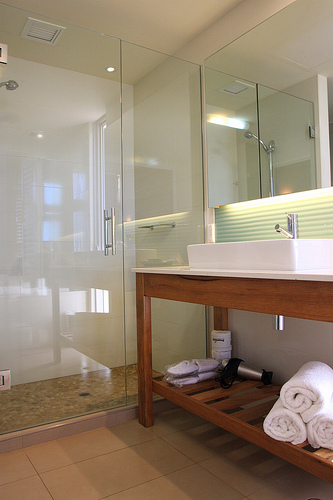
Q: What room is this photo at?
A: It is at the bathroom.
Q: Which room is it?
A: It is a bathroom.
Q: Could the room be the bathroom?
A: Yes, it is the bathroom.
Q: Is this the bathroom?
A: Yes, it is the bathroom.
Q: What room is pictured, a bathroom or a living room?
A: It is a bathroom.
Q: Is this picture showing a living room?
A: No, the picture is showing a bathroom.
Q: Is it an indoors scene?
A: Yes, it is indoors.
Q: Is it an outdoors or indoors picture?
A: It is indoors.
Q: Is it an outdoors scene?
A: No, it is indoors.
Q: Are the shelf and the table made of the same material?
A: Yes, both the shelf and the table are made of wood.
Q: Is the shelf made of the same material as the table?
A: Yes, both the shelf and the table are made of wood.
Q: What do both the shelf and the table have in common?
A: The material, both the shelf and the table are wooden.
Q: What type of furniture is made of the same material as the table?
A: The shelf is made of the same material as the table.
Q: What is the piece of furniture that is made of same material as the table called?
A: The piece of furniture is a shelf.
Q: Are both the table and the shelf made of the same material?
A: Yes, both the table and the shelf are made of wood.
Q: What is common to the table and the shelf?
A: The material, both the table and the shelf are wooden.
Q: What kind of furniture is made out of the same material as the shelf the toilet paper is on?
A: The table is made of the same material as the shelf.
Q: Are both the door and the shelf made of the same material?
A: No, the door is made of glass and the shelf is made of wood.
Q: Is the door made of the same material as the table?
A: No, the door is made of glass and the table is made of wood.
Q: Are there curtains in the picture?
A: No, there are no curtains.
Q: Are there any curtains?
A: No, there are no curtains.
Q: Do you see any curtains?
A: No, there are no curtains.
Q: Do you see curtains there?
A: No, there are no curtains.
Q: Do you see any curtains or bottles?
A: No, there are no curtains or bottles.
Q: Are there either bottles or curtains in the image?
A: No, there are no curtains or bottles.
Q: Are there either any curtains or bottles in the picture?
A: No, there are no curtains or bottles.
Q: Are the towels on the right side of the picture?
A: Yes, the towels are on the right of the image.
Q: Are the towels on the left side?
A: No, the towels are on the right of the image.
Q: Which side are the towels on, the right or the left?
A: The towels are on the right of the image.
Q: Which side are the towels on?
A: The towels are on the right of the image.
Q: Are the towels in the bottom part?
A: Yes, the towels are in the bottom of the image.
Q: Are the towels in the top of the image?
A: No, the towels are in the bottom of the image.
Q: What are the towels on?
A: The towels are on the shelf.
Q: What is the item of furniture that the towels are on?
A: The piece of furniture is a shelf.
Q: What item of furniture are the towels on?
A: The towels are on the shelf.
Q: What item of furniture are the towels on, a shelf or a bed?
A: The towels are on a shelf.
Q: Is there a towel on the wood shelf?
A: Yes, there are towels on the shelf.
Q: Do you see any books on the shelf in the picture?
A: No, there are towels on the shelf.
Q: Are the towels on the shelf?
A: Yes, the towels are on the shelf.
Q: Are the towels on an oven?
A: No, the towels are on the shelf.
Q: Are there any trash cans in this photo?
A: No, there are no trash cans.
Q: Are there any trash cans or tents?
A: No, there are no trash cans or tents.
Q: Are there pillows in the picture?
A: No, there are no pillows.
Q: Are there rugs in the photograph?
A: No, there are no rugs.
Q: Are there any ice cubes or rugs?
A: No, there are no rugs or ice cubes.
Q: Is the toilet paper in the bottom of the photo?
A: Yes, the toilet paper is in the bottom of the image.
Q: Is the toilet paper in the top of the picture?
A: No, the toilet paper is in the bottom of the image.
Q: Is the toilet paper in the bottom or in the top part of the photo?
A: The toilet paper is in the bottom of the image.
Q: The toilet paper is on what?
A: The toilet paper is on the shelf.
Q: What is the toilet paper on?
A: The toilet paper is on the shelf.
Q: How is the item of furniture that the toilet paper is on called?
A: The piece of furniture is a shelf.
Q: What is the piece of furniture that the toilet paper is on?
A: The piece of furniture is a shelf.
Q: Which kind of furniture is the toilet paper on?
A: The toilet paper is on the shelf.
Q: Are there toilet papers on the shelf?
A: Yes, there is a toilet paper on the shelf.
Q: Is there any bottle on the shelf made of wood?
A: No, there is a toilet paper on the shelf.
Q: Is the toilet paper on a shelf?
A: Yes, the toilet paper is on a shelf.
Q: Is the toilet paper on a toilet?
A: No, the toilet paper is on a shelf.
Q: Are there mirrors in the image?
A: Yes, there is a mirror.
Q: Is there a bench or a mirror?
A: Yes, there is a mirror.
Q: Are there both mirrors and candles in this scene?
A: No, there is a mirror but no candles.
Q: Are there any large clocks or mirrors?
A: Yes, there is a large mirror.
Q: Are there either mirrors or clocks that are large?
A: Yes, the mirror is large.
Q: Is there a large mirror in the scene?
A: Yes, there is a large mirror.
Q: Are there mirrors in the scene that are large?
A: Yes, there is a mirror that is large.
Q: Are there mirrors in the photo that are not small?
A: Yes, there is a large mirror.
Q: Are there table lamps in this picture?
A: No, there are no table lamps.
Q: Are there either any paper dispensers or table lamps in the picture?
A: No, there are no table lamps or paper dispensers.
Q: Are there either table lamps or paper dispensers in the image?
A: No, there are no table lamps or paper dispensers.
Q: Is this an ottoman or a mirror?
A: This is a mirror.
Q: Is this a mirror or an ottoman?
A: This is a mirror.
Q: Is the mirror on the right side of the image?
A: Yes, the mirror is on the right of the image.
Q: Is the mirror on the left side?
A: No, the mirror is on the right of the image.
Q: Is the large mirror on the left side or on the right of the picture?
A: The mirror is on the right of the image.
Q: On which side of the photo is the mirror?
A: The mirror is on the right of the image.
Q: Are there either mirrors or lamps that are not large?
A: No, there is a mirror but it is large.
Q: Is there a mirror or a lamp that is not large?
A: No, there is a mirror but it is large.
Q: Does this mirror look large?
A: Yes, the mirror is large.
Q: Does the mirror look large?
A: Yes, the mirror is large.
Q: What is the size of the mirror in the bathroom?
A: The mirror is large.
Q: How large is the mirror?
A: The mirror is large.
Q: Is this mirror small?
A: No, the mirror is large.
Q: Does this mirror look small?
A: No, the mirror is large.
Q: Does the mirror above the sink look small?
A: No, the mirror is large.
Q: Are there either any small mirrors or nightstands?
A: No, there is a mirror but it is large.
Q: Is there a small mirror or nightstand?
A: No, there is a mirror but it is large.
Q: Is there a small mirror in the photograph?
A: No, there is a mirror but it is large.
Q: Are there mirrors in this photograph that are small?
A: No, there is a mirror but it is large.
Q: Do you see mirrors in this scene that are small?
A: No, there is a mirror but it is large.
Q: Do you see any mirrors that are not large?
A: No, there is a mirror but it is large.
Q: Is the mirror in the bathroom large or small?
A: The mirror is large.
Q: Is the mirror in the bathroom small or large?
A: The mirror is large.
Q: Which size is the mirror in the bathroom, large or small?
A: The mirror is large.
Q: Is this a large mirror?
A: Yes, this is a large mirror.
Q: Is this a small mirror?
A: No, this is a large mirror.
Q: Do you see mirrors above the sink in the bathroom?
A: Yes, there is a mirror above the sink.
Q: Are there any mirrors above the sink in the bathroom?
A: Yes, there is a mirror above the sink.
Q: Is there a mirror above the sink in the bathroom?
A: Yes, there is a mirror above the sink.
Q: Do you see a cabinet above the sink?
A: No, there is a mirror above the sink.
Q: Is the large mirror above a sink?
A: Yes, the mirror is above a sink.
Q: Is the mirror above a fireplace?
A: No, the mirror is above a sink.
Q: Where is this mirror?
A: The mirror is in the bathroom.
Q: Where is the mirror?
A: The mirror is in the bathroom.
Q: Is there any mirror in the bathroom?
A: Yes, there is a mirror in the bathroom.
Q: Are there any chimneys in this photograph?
A: No, there are no chimneys.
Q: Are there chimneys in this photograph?
A: No, there are no chimneys.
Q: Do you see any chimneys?
A: No, there are no chimneys.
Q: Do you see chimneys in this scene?
A: No, there are no chimneys.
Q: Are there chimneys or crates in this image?
A: No, there are no chimneys or crates.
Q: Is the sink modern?
A: Yes, the sink is modern.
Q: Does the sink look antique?
A: No, the sink is modern.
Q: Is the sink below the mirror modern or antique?
A: The sink is modern.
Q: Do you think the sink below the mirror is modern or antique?
A: The sink is modern.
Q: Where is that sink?
A: The sink is in the bathroom.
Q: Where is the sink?
A: The sink is in the bathroom.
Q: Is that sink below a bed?
A: No, the sink is below the mirror.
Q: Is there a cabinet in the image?
A: No, there are no cabinets.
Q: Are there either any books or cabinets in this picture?
A: No, there are no cabinets or books.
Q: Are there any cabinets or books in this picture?
A: No, there are no cabinets or books.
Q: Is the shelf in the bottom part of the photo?
A: Yes, the shelf is in the bottom of the image.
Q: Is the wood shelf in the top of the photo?
A: No, the shelf is in the bottom of the image.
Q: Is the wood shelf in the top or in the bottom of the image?
A: The shelf is in the bottom of the image.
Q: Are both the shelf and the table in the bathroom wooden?
A: Yes, both the shelf and the table are wooden.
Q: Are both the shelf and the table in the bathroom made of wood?
A: Yes, both the shelf and the table are made of wood.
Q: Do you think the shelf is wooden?
A: Yes, the shelf is wooden.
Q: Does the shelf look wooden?
A: Yes, the shelf is wooden.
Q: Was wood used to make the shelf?
A: Yes, the shelf is made of wood.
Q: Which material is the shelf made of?
A: The shelf is made of wood.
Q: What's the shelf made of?
A: The shelf is made of wood.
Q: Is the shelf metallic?
A: No, the shelf is wooden.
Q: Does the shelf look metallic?
A: No, the shelf is wooden.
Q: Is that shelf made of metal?
A: No, the shelf is made of wood.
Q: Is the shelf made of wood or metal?
A: The shelf is made of wood.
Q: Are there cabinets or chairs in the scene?
A: No, there are no chairs or cabinets.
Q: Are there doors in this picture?
A: Yes, there is a door.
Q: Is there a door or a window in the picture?
A: Yes, there is a door.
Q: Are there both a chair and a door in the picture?
A: No, there is a door but no chairs.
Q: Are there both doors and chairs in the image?
A: No, there is a door but no chairs.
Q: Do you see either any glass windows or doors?
A: Yes, there is a glass door.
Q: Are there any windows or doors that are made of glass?
A: Yes, the door is made of glass.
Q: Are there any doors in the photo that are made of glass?
A: Yes, there is a door that is made of glass.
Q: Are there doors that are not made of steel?
A: Yes, there is a door that is made of glass.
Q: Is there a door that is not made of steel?
A: Yes, there is a door that is made of glass.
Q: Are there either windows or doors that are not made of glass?
A: No, there is a door but it is made of glass.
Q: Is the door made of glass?
A: Yes, the door is made of glass.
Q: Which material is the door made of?
A: The door is made of glass.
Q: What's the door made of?
A: The door is made of glass.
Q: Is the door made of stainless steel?
A: No, the door is made of glass.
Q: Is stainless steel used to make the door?
A: No, the door is made of glass.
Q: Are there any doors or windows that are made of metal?
A: No, there is a door but it is made of glass.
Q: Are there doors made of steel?
A: No, there is a door but it is made of glass.